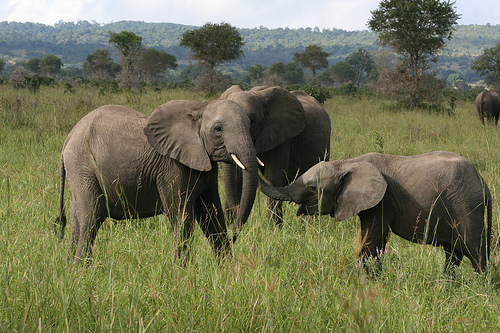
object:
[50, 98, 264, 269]
elephant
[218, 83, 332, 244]
elephant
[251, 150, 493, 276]
elephant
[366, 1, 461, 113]
tree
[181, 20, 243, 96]
tree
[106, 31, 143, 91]
tree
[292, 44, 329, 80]
tree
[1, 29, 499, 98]
forest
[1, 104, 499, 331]
grasslands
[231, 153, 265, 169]
tusks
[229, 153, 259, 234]
trunk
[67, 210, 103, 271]
feet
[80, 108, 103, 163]
indentation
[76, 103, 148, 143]
back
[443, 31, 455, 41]
leaves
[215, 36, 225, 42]
leaves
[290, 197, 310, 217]
mouth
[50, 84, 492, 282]
family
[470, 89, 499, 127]
elephant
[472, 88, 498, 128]
away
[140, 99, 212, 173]
ear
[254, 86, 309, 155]
ear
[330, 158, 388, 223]
ear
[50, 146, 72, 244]
tail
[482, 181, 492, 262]
tail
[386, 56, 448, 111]
bottom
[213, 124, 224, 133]
eye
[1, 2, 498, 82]
distance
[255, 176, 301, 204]
trunk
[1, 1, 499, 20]
sky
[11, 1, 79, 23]
clouds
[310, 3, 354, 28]
clouds